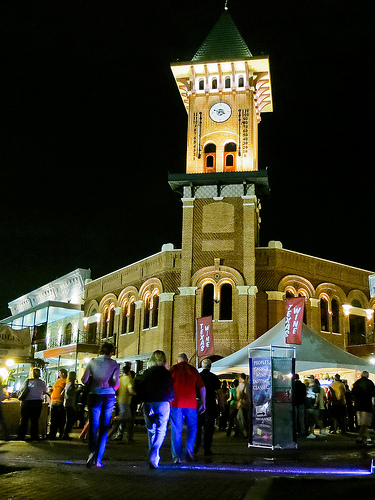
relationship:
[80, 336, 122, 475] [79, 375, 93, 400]
person has purse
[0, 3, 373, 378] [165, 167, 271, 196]
building has balcony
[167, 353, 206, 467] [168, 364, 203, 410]
man wearing shirt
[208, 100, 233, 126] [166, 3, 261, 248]
clock on clock tower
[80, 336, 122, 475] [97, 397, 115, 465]
person has legs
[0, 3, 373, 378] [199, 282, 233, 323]
building has windows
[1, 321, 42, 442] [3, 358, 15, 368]
booth has lights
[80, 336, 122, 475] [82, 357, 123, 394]
person wearing shirt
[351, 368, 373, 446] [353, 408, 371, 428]
man wearing shorts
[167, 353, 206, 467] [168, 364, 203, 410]
man has shirt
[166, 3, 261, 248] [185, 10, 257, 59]
clock tower has roof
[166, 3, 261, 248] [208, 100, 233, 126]
clock tower has clock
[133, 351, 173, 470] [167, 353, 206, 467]
woman behind man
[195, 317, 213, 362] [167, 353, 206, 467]
sign above man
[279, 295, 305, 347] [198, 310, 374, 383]
sign on tent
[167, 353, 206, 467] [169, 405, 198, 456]
man wearing jeans